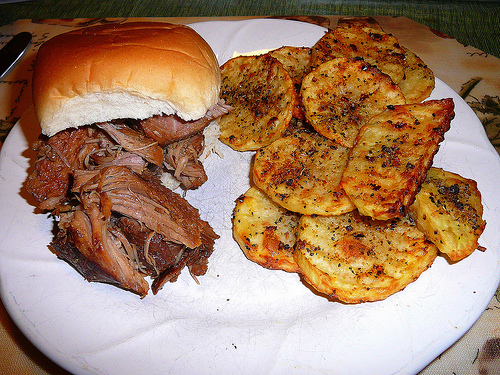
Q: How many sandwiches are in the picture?
A: One.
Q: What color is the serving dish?
A: White.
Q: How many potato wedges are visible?
A: Nine.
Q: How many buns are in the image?
A: One.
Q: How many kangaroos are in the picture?
A: Zero.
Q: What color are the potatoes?
A: Yellow.